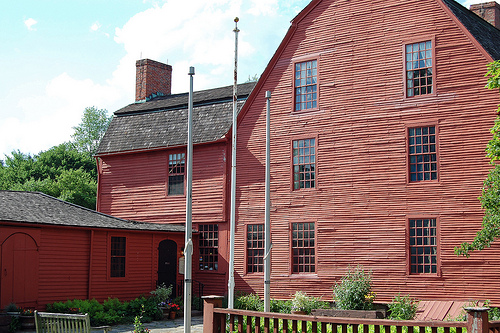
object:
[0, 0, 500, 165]
sky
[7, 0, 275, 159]
some clouds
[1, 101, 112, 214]
tree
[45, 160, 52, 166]
leaves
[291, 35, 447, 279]
several windows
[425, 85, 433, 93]
window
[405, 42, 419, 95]
curtains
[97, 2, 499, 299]
wall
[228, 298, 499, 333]
grass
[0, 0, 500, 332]
barn house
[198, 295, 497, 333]
fence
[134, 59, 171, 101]
chimney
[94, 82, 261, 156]
rooftop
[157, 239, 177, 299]
coal door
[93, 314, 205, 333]
walkway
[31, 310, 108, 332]
park bench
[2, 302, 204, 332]
patio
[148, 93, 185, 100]
shadow cast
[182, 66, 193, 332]
pole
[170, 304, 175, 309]
flower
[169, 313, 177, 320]
pot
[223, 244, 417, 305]
bushes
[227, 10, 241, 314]
poles